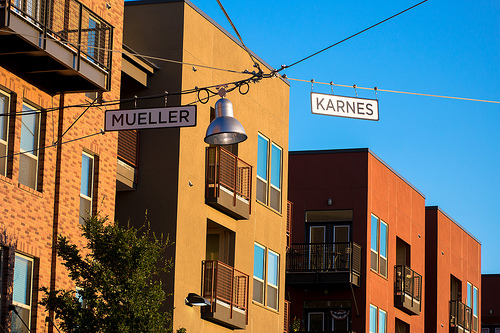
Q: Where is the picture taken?
A: A street.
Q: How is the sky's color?
A: Clear blue.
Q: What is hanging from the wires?
A: Signs.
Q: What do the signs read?
A: Mueller and Karnes.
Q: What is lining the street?
A: Buildings.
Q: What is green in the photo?
A: A tree.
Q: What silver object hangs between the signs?
A: A lamp.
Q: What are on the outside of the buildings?
A: Balconies.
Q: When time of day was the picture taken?
A: Afternoon.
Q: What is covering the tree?
A: Green leaves.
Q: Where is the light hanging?
A: Between street signs.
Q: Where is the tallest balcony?
A: Brick building.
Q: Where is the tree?
A: In front of brick building.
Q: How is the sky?
A: Clear.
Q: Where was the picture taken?
A: At the crossing of Mueller and Karnes streets.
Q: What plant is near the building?
A: A tree.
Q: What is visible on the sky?
A: Power lines.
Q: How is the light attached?
A: Hanging on the wire.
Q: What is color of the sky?
A: Blue.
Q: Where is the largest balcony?
A: In the top left corner.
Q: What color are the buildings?
A: Brown.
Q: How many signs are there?
A: Two.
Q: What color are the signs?
A: White.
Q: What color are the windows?
A: Blue.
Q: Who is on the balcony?
A: No one.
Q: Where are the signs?
A: Electric wire.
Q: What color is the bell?
A: Silver.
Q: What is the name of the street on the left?
A: Mueller.